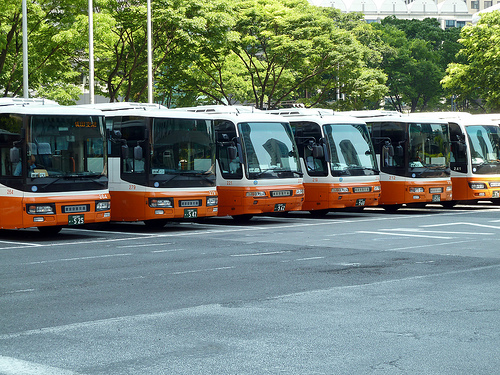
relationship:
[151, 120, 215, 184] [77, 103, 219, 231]
windshield on bus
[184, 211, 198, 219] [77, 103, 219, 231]
license plate on bus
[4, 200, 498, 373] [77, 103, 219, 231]
lot with bus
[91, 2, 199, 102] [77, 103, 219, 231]
tree behind bus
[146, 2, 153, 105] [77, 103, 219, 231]
pole behind bus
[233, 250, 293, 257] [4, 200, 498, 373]
mark on lot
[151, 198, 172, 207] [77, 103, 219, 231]
light on bus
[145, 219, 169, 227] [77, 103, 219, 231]
tire on bus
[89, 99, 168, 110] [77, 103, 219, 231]
unit on bus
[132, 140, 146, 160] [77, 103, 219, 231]
mirror on bus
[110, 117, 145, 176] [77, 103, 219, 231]
window of bus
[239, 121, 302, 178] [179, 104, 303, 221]
windshield of bus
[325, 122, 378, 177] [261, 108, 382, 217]
windshield of bus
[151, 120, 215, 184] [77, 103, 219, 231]
windshield of bus